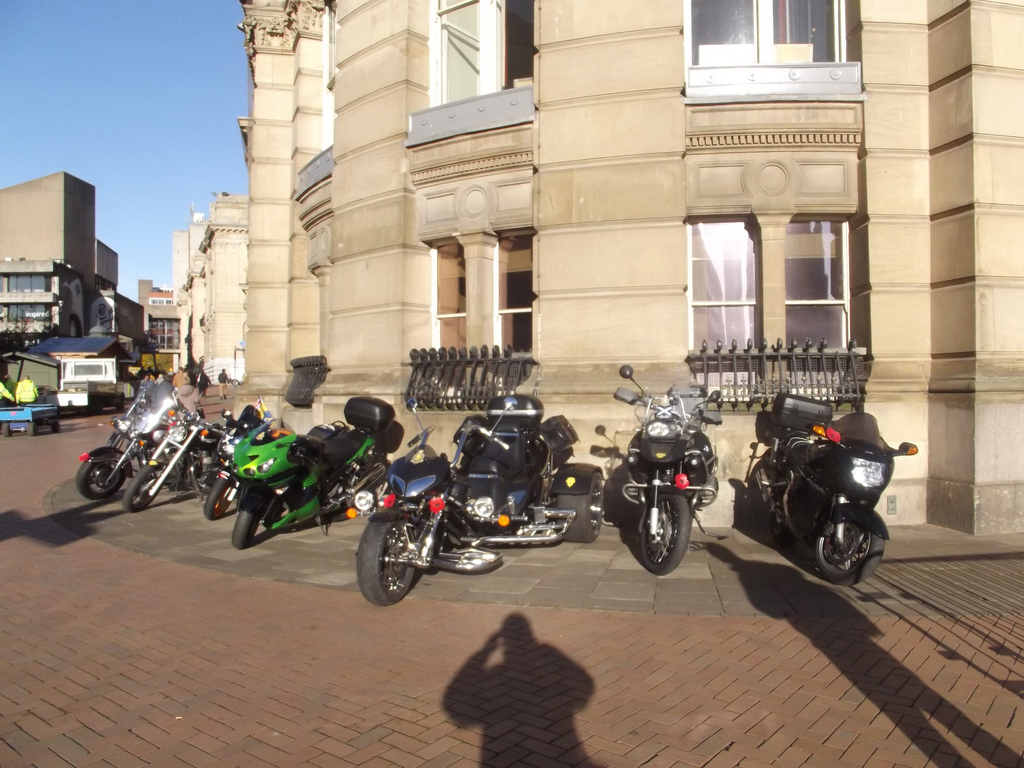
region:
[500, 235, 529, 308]
glass is clean and clear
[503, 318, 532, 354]
glass is clean and clear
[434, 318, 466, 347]
glass is clean and clear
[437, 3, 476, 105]
glass is clean and clear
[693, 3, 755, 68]
glass is clean and clear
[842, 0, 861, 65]
glass is clean and clear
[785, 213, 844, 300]
glass window on the building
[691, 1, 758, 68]
glass window on the building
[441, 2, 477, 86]
glass window on the building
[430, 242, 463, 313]
glass window on the building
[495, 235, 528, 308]
glass window on the building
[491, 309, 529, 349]
glass window on the building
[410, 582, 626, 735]
man's reflection on the pavement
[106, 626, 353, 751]
red tiles on the ground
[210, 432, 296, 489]
green and yellow color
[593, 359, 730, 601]
black bike parked in the spot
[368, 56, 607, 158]
balcony at the window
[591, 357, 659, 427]
mirrors on the bike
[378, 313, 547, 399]
black iron railing on front of building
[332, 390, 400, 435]
container at end of bike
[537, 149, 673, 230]
brown stone on the wall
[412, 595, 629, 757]
shadow of a person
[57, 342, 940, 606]
the motorcycles are parked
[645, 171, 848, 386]
the windows are closed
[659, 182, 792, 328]
the sun is on the window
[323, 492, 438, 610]
the wheel is black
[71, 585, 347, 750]
the ground is brown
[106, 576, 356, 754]
the ground is made of brick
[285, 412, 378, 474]
the seat is black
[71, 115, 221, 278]
no clouds in the sky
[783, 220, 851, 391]
A window on a building.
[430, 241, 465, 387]
A window on a building.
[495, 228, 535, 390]
A window on a building.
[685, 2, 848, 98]
A window on a building.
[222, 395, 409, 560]
green motorcycle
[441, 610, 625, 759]
black shadow of photographer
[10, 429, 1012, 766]
red brick sidewalk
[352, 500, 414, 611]
black front motorcycle tire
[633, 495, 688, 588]
black front motorcycle tire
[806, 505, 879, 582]
black front motorcycle tire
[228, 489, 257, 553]
black front motorcycle tire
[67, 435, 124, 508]
black front motorcycle tire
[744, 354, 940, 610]
large black motorcycle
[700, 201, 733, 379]
a window on the building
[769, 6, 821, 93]
a window on the building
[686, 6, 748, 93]
a window on the building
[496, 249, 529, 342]
a window on the building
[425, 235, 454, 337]
a window on the building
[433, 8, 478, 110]
a window on the building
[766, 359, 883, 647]
a bike on the sidewalk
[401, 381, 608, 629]
a bike on the sidewalk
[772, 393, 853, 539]
a bike on the sidewalk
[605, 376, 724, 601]
a bike on the sidewalkv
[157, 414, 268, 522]
a bike on the sidewalk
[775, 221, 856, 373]
a window on the building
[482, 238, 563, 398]
a window on the building